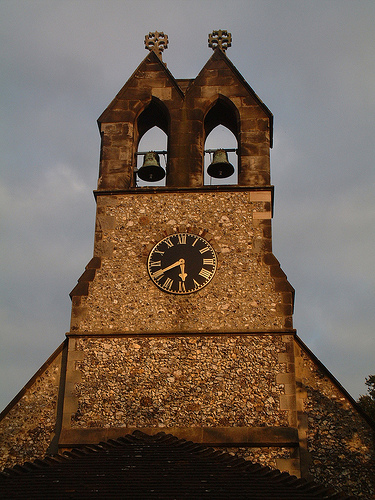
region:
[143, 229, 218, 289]
Large black metal clock face with brass hands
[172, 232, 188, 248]
Roman numeral in a golden color on a black background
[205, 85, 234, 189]
Metal bell hanging from a pole with a descending ringer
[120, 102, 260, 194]
Two metal bells at the top of a church tower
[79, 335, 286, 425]
Wall made of varying colors of many shaped stones and pebbles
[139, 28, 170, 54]
Metal spire built on the roof of a church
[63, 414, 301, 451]
Thick dark brown wooden beam across a stone building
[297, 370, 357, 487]
Shadows cast on the wall of a building made of many stones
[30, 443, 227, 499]
Black shingles of a roof covered in leaves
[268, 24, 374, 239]
Cloudy pale blue sky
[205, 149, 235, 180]
Bell on large brick building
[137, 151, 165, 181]
Bell on large brick building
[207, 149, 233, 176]
Bell next to bell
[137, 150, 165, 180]
Bell next to bell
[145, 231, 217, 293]
Large round clock on building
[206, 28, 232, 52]
Ornate decor on top of the building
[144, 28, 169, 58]
Ornate decor on top of the building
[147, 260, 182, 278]
Large golden minute hand on clock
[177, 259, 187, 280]
Small golden hour hand on clock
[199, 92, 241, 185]
Arched space on building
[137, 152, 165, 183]
Metal bell in clock tower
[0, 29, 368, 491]
Stone and brick clock tower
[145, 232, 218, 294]
Time of 5:40 on clock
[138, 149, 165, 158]
Shaft holding tower bell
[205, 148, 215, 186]
Pull rope of bell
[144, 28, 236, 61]
Scu;lptures on top of clock tower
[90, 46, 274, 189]
Cement block constructed belfry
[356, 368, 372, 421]
Leaf covered tree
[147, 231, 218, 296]
Round clock face on tower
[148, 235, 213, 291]
Roman numerals on clock face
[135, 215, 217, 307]
a big black clock on a church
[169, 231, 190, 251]
the roman numeral for twelve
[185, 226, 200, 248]
the roman numeral for one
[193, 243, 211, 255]
the roman numeral for two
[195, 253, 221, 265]
the roman numeral for three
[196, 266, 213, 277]
the roman numeral for four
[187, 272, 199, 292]
the roman numeral for five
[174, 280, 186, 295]
the roman numeral for six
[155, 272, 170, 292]
the roman numeral for seven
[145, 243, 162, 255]
the roman numeral for ten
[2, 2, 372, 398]
cloud cover in sky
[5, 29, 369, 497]
clock tower with bells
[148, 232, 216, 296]
clock with black face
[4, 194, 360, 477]
stones in clocktower wall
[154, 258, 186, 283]
two gold clock hands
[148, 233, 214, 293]
roman numerals on clock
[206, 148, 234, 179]
bell hanging from pole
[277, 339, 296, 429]
blocks of stone on tower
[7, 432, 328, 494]
slanted roof in front of tower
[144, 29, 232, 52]
design elements on tower